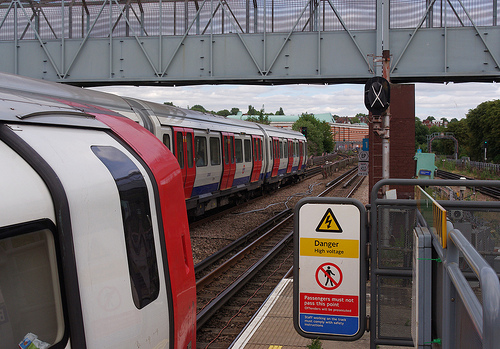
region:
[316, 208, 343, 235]
the emblem is yellow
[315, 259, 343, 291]
the emblem has a red circle with a line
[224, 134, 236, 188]
the doors are red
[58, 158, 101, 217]
the train is white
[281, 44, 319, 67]
the bridge is gray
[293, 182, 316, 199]
the cords are on the ground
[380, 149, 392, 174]
the pole is silver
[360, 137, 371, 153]
the sign is blue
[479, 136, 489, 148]
the light is green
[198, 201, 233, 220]
the train is on the tracks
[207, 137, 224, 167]
window on the train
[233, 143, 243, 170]
window on the train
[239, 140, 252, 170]
window on the train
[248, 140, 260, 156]
window on the train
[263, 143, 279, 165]
window on the train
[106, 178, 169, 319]
window on the train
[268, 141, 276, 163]
window on the train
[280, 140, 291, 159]
window on the train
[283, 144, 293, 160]
window on the train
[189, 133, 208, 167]
window on the train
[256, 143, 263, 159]
window on the train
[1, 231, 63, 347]
window on the train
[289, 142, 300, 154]
window on the train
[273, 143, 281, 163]
window on the train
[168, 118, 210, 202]
the door is red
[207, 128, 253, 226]
the door is red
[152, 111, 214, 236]
the door is red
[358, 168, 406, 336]
the pole is black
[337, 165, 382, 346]
the pole is black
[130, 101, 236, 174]
A train in the photo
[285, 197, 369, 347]
Signage in the photo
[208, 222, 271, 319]
Railway track in the photo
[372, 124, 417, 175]
A pole in the photo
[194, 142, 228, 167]
Windows on the train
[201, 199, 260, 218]
Wheels on the train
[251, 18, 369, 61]
A bridge in the photo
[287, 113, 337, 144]
A tree in the photo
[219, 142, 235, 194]
A door on the train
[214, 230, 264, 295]
Track ballast in the photo